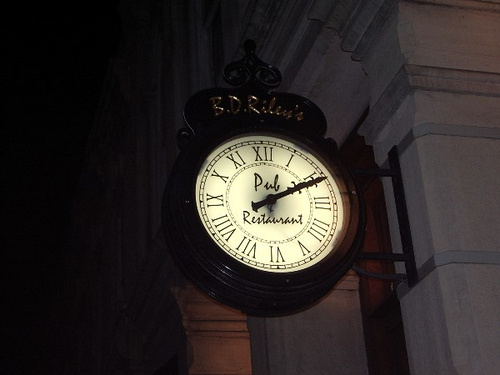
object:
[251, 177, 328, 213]
clockhand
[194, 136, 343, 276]
clock face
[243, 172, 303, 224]
script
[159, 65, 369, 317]
clock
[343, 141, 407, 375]
door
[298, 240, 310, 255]
roman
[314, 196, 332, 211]
letters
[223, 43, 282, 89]
decoration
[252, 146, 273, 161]
12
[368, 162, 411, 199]
ground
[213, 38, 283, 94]
embellishment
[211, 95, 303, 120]
gold lettering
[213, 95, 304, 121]
name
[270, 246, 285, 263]
numeral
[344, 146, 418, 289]
mounting plate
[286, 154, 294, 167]
roman numerals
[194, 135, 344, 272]
face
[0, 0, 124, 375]
sky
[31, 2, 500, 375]
building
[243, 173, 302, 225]
saying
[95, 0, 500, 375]
pub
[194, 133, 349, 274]
face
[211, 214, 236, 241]
roman numeral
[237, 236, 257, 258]
roman numeral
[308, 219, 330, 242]
roman numeral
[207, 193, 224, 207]
roman numeral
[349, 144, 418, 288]
bar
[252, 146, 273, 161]
roman numeral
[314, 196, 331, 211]
roman numeral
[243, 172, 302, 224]
text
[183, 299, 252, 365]
light